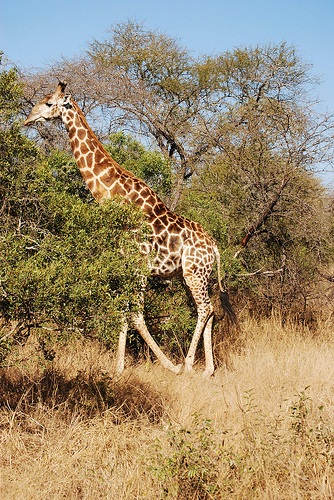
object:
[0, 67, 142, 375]
greentree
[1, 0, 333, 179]
blue sky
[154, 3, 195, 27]
white clouds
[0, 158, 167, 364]
bush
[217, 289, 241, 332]
black tail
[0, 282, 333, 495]
grass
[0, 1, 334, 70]
cloud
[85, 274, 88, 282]
leaves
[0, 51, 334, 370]
tree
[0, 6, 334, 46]
sky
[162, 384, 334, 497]
plant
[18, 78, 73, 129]
head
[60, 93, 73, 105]
ear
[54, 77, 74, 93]
horns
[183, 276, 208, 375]
leg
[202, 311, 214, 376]
leg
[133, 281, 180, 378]
leg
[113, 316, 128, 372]
leg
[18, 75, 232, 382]
giraffe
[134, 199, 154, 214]
spots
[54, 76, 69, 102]
ossicles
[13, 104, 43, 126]
nose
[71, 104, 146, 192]
mane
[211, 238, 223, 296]
tail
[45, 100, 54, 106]
eye